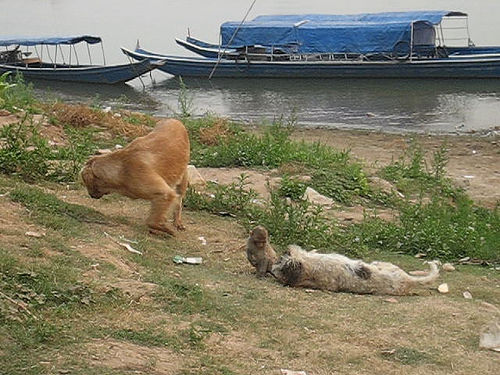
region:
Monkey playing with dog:
[245, 221, 280, 288]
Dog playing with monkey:
[271, 232, 446, 298]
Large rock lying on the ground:
[300, 186, 335, 216]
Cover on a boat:
[217, 21, 442, 54]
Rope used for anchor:
[122, 48, 146, 90]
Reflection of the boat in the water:
[153, 78, 481, 122]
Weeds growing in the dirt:
[372, 136, 480, 196]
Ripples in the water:
[207, 79, 266, 105]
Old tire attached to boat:
[385, 37, 415, 64]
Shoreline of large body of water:
[240, 98, 466, 152]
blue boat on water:
[130, 31, 498, 141]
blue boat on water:
[281, 1, 441, 118]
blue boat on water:
[232, 10, 389, 105]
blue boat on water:
[141, 12, 331, 154]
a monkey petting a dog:
[239, 223, 279, 277]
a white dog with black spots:
[268, 245, 447, 305]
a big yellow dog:
[66, 110, 196, 250]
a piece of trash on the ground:
[161, 250, 211, 272]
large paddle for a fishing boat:
[198, 1, 267, 84]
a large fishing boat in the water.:
[121, 6, 498, 93]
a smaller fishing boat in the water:
[0, 33, 160, 89]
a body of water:
[0, 1, 494, 142]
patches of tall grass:
[0, 68, 496, 266]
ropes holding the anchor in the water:
[113, 39, 189, 97]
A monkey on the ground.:
[229, 219, 279, 281]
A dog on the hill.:
[41, 104, 220, 275]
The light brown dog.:
[69, 98, 207, 251]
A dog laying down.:
[279, 231, 457, 321]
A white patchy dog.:
[272, 237, 450, 307]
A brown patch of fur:
[345, 259, 380, 288]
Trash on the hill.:
[50, 95, 125, 154]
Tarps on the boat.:
[218, 0, 460, 57]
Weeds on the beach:
[175, 89, 298, 162]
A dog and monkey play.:
[237, 212, 447, 296]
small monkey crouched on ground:
[243, 223, 276, 277]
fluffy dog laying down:
[273, 240, 440, 302]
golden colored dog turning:
[76, 117, 201, 239]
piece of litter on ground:
[166, 249, 212, 269]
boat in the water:
[111, 7, 498, 102]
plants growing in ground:
[256, 175, 498, 257]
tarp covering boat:
[212, 11, 467, 54]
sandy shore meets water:
[234, 131, 498, 171]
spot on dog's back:
[352, 264, 374, 280]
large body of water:
[62, 77, 497, 129]